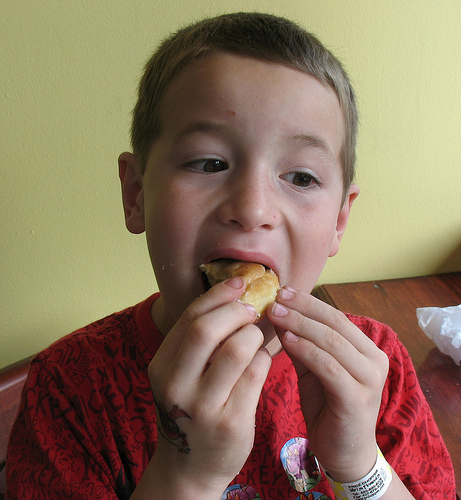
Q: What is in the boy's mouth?
A: Sandwich.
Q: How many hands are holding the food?
A: 2.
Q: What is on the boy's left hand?
A: Fake tattoo.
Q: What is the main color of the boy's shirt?
A: Red.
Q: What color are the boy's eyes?
A: Brown.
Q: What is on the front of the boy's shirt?
A: A sticker.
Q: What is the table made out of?
A: Wood.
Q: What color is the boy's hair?
A: Brown.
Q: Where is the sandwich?
A: In his mouth.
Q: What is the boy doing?
A: Eating.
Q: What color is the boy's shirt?
A: Red.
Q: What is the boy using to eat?
A: Hands.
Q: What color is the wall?
A: Yellow.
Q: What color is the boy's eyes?
A: Brown.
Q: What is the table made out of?
A: Wood.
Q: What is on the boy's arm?
A: A wristband.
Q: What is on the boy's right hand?
A: A tattoo.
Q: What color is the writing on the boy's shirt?
A: Black.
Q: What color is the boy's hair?
A: Brown.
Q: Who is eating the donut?
A: Boy.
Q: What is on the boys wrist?
A: Wristband.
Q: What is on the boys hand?
A: Temporary Tattoo.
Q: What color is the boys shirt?
A: Red.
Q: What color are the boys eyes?
A: Brown.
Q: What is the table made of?
A: Wood.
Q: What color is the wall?
A: Yellow.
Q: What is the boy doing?
A: Eating.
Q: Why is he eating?
A: He is hungry.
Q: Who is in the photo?
A: A boy.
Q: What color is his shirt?
A: Red.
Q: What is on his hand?
A: Temporary tattoo.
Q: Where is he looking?
A: Down and to the left.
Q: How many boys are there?
A: One.